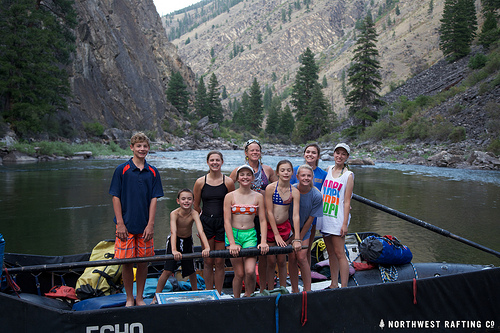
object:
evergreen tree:
[166, 67, 189, 113]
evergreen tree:
[350, 10, 381, 132]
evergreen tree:
[297, 47, 325, 138]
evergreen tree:
[233, 77, 263, 134]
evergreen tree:
[202, 73, 226, 124]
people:
[106, 131, 356, 309]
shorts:
[266, 219, 291, 242]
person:
[192, 150, 234, 294]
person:
[228, 139, 278, 192]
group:
[107, 132, 354, 307]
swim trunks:
[162, 237, 195, 278]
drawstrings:
[180, 238, 184, 251]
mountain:
[0, 0, 178, 144]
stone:
[127, 30, 165, 114]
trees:
[165, 0, 500, 140]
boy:
[107, 131, 164, 307]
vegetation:
[0, 0, 77, 134]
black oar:
[2, 245, 307, 275]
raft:
[1, 245, 499, 331]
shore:
[324, 135, 459, 164]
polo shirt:
[108, 156, 163, 233]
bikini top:
[231, 204, 258, 214]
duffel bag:
[75, 241, 122, 300]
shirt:
[199, 171, 230, 217]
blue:
[390, 250, 407, 263]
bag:
[360, 235, 413, 265]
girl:
[319, 144, 355, 290]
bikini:
[272, 181, 293, 205]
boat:
[0, 246, 500, 332]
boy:
[150, 187, 209, 303]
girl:
[223, 165, 269, 297]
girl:
[264, 160, 302, 290]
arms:
[170, 217, 176, 249]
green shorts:
[225, 228, 258, 248]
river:
[0, 149, 498, 263]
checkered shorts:
[114, 232, 155, 259]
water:
[18, 166, 73, 222]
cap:
[334, 143, 350, 155]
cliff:
[81, 0, 205, 136]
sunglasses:
[247, 139, 260, 145]